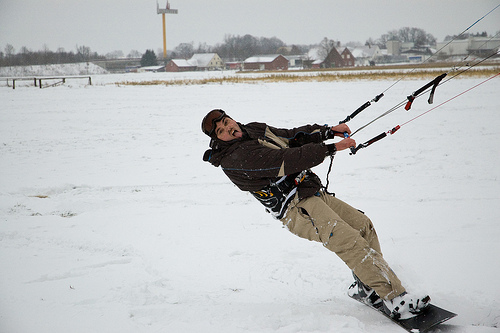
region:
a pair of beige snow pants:
[280, 187, 402, 302]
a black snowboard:
[345, 273, 457, 329]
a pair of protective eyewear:
[199, 108, 226, 133]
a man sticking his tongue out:
[212, 117, 242, 143]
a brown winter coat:
[201, 117, 336, 219]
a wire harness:
[336, 0, 497, 156]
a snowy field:
[0, 85, 498, 330]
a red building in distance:
[242, 53, 290, 71]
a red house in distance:
[305, 44, 343, 69]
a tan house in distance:
[191, 50, 221, 70]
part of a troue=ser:
[355, 232, 377, 266]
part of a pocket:
[267, 175, 317, 242]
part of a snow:
[147, 187, 192, 247]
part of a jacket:
[253, 188, 285, 240]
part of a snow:
[190, 243, 232, 298]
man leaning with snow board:
[187, 89, 452, 330]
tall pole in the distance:
[154, 1, 184, 66]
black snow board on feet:
[338, 270, 458, 328]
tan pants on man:
[300, 180, 409, 292]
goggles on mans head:
[200, 102, 227, 138]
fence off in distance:
[2, 63, 104, 98]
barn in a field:
[245, 53, 293, 71]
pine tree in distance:
[140, 46, 160, 73]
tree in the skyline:
[387, 25, 434, 40]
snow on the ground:
[42, 163, 217, 275]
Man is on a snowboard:
[195, 100, 465, 330]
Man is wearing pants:
[271, 188, 410, 305]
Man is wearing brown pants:
[278, 187, 409, 301]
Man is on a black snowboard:
[346, 279, 462, 330]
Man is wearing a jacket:
[189, 122, 336, 222]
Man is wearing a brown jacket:
[198, 118, 340, 213]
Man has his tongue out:
[225, 128, 245, 138]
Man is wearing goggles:
[197, 107, 224, 137]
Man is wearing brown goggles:
[196, 106, 226, 138]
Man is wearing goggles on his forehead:
[197, 107, 227, 138]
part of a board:
[426, 303, 437, 320]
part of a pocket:
[329, 176, 355, 206]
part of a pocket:
[289, 193, 306, 233]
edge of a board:
[431, 302, 447, 326]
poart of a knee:
[329, 218, 355, 313]